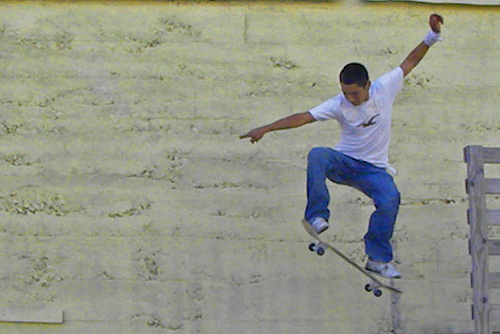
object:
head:
[335, 59, 377, 107]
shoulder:
[325, 92, 342, 125]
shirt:
[307, 66, 405, 176]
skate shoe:
[363, 256, 402, 281]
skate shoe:
[312, 212, 331, 234]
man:
[268, 61, 482, 282]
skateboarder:
[225, 28, 452, 298]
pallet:
[462, 142, 496, 332]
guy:
[240, 12, 444, 278]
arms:
[240, 12, 442, 142]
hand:
[427, 12, 444, 33]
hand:
[237, 130, 264, 142]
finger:
[235, 132, 249, 140]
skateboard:
[298, 214, 404, 296]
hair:
[336, 61, 370, 88]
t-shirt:
[307, 66, 404, 178]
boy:
[238, 13, 443, 278]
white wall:
[24, 31, 229, 288]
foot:
[250, 211, 417, 281]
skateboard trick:
[287, 223, 424, 332]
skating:
[281, 118, 431, 300]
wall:
[4, 4, 498, 332]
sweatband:
[424, 30, 440, 45]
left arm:
[388, 13, 443, 98]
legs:
[304, 142, 404, 272]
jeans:
[302, 145, 399, 264]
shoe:
[305, 217, 330, 238]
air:
[47, 39, 482, 332]